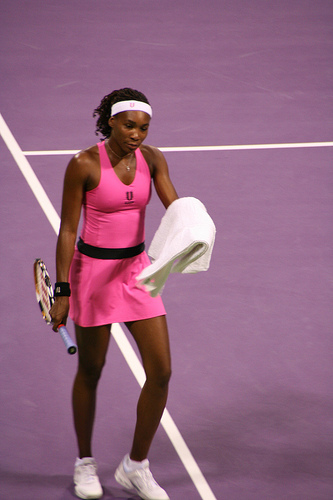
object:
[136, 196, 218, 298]
towel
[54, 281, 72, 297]
wrist band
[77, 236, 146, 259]
belt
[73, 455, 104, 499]
sneaker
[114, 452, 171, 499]
sneaker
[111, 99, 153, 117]
head band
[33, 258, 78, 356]
tennis racquet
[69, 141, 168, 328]
dress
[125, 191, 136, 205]
logo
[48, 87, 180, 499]
girl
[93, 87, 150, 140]
hair